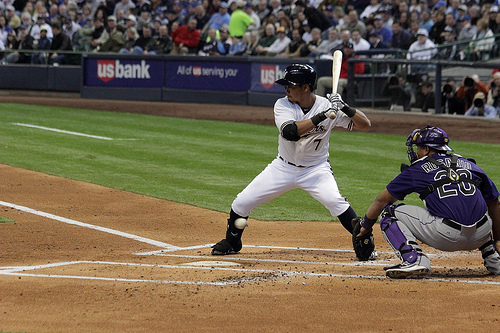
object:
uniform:
[231, 94, 356, 219]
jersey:
[384, 152, 500, 222]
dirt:
[1, 162, 498, 332]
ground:
[2, 101, 499, 332]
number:
[314, 139, 323, 151]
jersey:
[273, 95, 354, 166]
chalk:
[0, 200, 183, 253]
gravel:
[216, 265, 283, 297]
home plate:
[180, 260, 242, 267]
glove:
[352, 216, 376, 261]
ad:
[97, 61, 149, 83]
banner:
[83, 56, 250, 90]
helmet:
[275, 63, 318, 90]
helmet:
[407, 126, 455, 166]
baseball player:
[353, 125, 499, 280]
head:
[414, 125, 449, 159]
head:
[285, 63, 318, 102]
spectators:
[1, 2, 496, 119]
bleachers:
[1, 2, 498, 117]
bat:
[328, 49, 344, 120]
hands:
[323, 104, 339, 117]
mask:
[405, 137, 419, 163]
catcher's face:
[415, 143, 427, 157]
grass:
[0, 99, 500, 219]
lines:
[75, 259, 500, 286]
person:
[221, 0, 256, 42]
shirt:
[223, 10, 252, 37]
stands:
[2, 1, 499, 119]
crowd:
[1, 0, 493, 63]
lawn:
[2, 100, 497, 245]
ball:
[235, 218, 247, 229]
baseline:
[7, 169, 184, 263]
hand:
[356, 221, 371, 237]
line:
[0, 200, 180, 250]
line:
[153, 252, 360, 266]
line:
[0, 269, 227, 286]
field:
[4, 84, 498, 320]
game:
[0, 31, 492, 327]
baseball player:
[210, 62, 375, 260]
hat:
[275, 63, 318, 91]